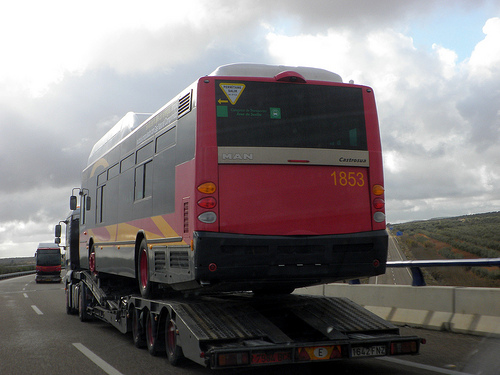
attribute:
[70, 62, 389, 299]
bus — red, black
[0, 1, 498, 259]
sky — cloudy, blue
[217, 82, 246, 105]
sign — triangular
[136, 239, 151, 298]
tire — round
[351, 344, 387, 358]
license plate — white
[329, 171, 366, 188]
numbers — yellow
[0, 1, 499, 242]
clouds — white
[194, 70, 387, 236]
back of bus — red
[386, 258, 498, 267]
rail — metal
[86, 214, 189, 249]
strip — yellow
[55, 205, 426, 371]
trailer — black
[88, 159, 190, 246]
design — red, yellow